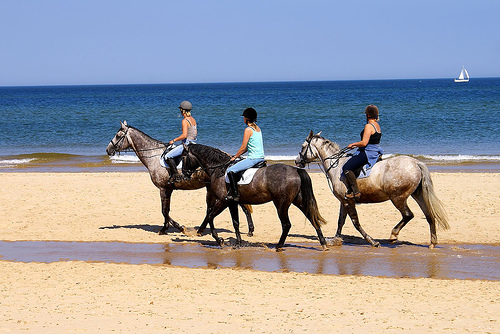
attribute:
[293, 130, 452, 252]
horse — white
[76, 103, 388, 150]
ocean water — bright, blue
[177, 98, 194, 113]
helmet — gray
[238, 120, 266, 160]
blue tank-top — baby blue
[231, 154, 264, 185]
saddle — black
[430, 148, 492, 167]
waves — gentle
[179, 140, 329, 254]
horse — brown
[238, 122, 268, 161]
blue top — striped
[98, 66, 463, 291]
horse — brown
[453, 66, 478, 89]
sail boat — white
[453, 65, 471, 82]
sailboat — white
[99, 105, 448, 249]
people — riding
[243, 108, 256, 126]
hair — dark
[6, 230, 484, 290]
sand — wet